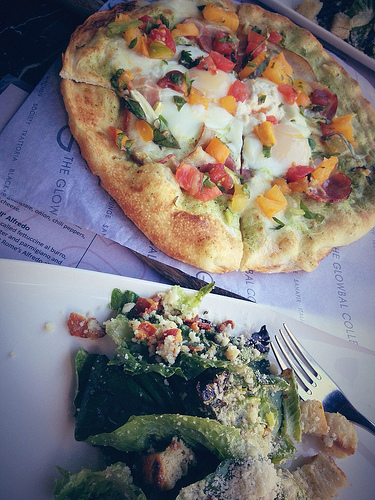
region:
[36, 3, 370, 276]
Freshly sliced pizza.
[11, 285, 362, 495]
Unfinished green salad.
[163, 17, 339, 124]
Pizza decorated with bacon, tomato and cheese.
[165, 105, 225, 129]
White melted cheese.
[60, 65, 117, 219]
Thin crusted pizza.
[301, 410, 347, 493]
Croutons mixed with the green salad.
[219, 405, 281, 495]
Cheese spread.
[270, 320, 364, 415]
Metallic fork on the edge of the green salad plate.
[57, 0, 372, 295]
Pizza on a straw plate covered with a layer of paper.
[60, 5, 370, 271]
Pizza with four slices.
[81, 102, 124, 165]
dry crust of pizza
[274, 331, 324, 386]
fork on white table top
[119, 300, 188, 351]
white cheese on green leaf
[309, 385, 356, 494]
croutons on white table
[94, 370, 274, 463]
green leaf on table top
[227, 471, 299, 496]
parmesan cheese on green leaf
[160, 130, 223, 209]
red tomato on pizza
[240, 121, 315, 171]
white cheese on pizza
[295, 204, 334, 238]
green scallions on pizza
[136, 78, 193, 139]
meat on slice of pizza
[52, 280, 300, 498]
a salad on a white plate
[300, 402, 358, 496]
garlic croutons on a white plate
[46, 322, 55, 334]
a bit of cheese on a white plate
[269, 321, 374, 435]
top of a stainless steel fork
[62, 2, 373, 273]
a pizza on a wrapping paper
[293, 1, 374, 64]
green salad and croutons on a plate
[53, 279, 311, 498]
green salad with sprinkled parmesan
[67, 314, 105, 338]
a bit of tomato with parmesan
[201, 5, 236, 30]
bit of a yellow pepper on a pizza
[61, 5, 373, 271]
a vegetarian pizza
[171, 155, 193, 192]
part of a tomto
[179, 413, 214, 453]
part of a veoin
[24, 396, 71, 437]
part of a plate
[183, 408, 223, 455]
edge of a leaf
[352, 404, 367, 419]
edge of a leaf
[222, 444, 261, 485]
part of an assh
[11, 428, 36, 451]
part of a plate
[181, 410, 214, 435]
edge of a leaf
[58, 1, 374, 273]
Pizza with cheese and vegetables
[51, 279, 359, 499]
A green salad with grated cheese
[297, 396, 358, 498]
Three crispy croutons with cheese on them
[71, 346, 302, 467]
A big green leaf of lettuce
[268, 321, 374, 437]
Metal fork resting on a plate of food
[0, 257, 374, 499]
A large white plate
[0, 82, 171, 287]
A partial restaurant menu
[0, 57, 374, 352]
A food grade tissue liner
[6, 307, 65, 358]
Crumbs of food on a white plate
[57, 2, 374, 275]
Golden baked pizza crust